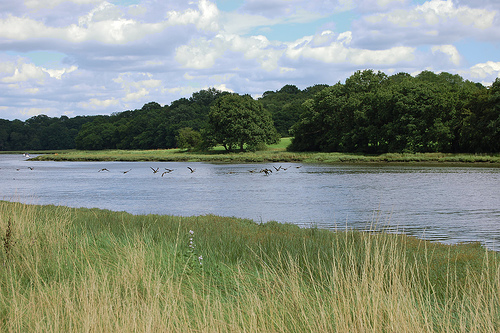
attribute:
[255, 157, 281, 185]
bird — flying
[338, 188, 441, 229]
water — blue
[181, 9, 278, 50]
sky — blue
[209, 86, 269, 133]
tree — green